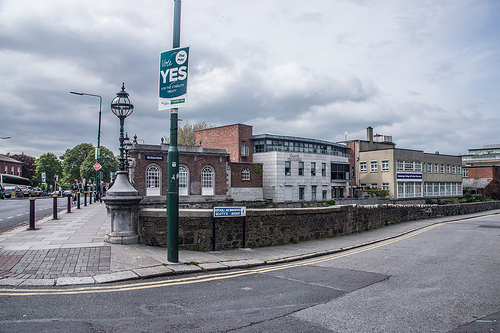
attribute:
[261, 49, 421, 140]
clouds — white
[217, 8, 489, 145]
sky — blue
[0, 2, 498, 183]
sky — blue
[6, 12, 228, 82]
cloud — white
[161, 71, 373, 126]
cloud — white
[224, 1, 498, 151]
cloud — white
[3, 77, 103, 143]
cloud — white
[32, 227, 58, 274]
sidewalk — stone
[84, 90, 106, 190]
lamp post — tall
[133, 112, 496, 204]
buildings — brick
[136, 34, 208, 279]
post — green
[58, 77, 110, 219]
light — tall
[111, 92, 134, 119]
globe — clear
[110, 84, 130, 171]
post — metal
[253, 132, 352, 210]
building — brick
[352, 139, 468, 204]
building — brick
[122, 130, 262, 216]
building — brick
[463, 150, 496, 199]
building — brick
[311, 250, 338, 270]
line — yellow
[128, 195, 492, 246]
wall — stone, short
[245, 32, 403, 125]
white clouds — blue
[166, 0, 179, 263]
post — green, tall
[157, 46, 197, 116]
sign — blue, white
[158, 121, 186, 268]
metal post — green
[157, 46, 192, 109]
advertisement — green, white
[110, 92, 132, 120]
lamp — black, metal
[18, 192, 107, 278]
side walk — stone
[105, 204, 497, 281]
sidewalk — concrete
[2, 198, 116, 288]
sidewalk — stone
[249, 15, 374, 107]
sky — blue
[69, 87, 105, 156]
lamp — tall, off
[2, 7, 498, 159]
clouds — white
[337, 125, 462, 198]
building — tan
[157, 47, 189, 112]
sign — green, political, white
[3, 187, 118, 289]
sidewalk — concrete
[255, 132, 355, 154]
top — a roof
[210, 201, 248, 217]
board — colorful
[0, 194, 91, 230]
road — paved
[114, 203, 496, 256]
wall — stone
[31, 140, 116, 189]
trees — green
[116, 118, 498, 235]
buildings — brick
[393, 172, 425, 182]
sign — blue, white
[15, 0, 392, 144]
clouds — white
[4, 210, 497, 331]
street — paved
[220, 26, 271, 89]
cloud — white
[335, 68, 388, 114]
cloud — white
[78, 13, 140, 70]
cloud — white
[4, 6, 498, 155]
sky — blue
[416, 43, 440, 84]
cloud — white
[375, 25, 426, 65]
cloud — white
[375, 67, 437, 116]
cloud — white